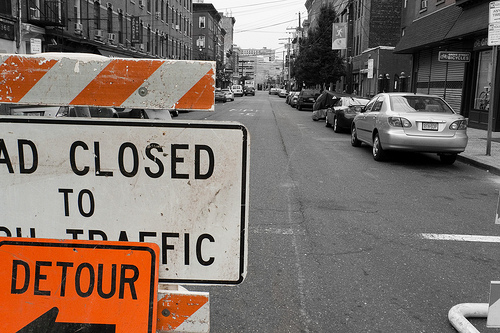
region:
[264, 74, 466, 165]
Line of cars in road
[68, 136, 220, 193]
Word closed on sign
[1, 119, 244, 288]
Rectangle sign is white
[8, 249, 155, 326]
Orange detour sign is square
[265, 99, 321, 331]
Line down middle of road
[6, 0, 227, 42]
Buildings alongside of road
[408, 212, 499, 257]
White stripe on side of road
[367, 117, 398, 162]
Back left tire of car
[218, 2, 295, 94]
Sky is white and hazy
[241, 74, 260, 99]
Bus far in background on road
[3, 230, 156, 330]
orange and black detour sign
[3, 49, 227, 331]
orange and white traffic barrier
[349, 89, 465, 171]
silver car parked on street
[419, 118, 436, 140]
license plate of silver car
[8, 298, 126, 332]
black arrow on orange detour sign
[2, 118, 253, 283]
white sign with black lettering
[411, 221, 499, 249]
white stripe painted on street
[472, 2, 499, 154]
street sign beside silver car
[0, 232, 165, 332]
detour signed leaned against other signs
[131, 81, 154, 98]
silver bolt on orange and white traffic barrier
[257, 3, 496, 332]
several cars parked on the side of a street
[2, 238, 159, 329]
an orange and black detour sign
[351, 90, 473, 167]
a silver passenger car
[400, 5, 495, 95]
the facade of a building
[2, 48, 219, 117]
an orange and white caution sign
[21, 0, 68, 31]
the balcony on a city building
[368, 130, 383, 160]
the rear tire of a car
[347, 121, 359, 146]
the front tire of a car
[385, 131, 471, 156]
the rear bumper of a car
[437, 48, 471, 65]
a sign outside of a city building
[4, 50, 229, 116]
orange and white stripes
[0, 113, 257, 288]
black and white sign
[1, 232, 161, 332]
orange and black sign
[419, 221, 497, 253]
white line painted on the ground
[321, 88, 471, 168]
cars parked along the side of the road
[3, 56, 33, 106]
white specks in the orange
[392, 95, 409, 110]
light shining on the window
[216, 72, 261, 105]
cars on the road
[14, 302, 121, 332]
top of a black arrow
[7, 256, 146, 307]
black writing in all caps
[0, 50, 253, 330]
directional signs are on the street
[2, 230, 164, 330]
the sign is orange with black letters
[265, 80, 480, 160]
cars are parked on the side of the road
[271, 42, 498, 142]
shops are along the road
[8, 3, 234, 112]
apartment buildings are next to the road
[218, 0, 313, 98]
wires are on poles over the street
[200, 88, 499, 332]
the street is paved with white markings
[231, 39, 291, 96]
buildings are at the end of the road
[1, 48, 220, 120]
an orange and white barrier are on the road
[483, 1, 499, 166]
a sign is on a sidewalk